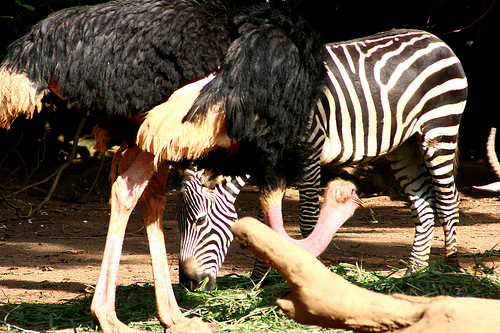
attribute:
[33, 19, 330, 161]
feathers — brown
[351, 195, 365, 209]
nose — orange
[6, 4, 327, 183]
feathers — black and brown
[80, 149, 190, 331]
legs — pink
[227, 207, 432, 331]
trunk — wooden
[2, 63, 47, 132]
tail — yellow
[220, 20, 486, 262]
zebra — black, white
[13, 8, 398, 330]
ostrich — curious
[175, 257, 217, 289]
muzzle — black, brown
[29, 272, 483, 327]
grass — green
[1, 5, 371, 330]
ostrcih — big, bird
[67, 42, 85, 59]
feather — black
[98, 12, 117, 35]
feather — black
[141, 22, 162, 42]
feather — black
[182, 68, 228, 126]
feather — black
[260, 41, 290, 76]
feather — black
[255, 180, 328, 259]
neck — curved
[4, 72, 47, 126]
fur — yellow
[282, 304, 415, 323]
log —  brown